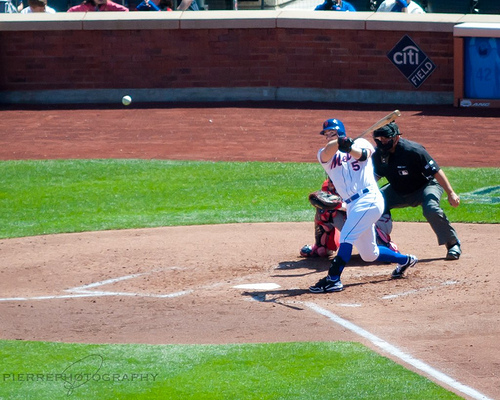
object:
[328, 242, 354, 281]
socks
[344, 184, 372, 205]
belt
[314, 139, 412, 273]
uniform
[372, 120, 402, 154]
facemask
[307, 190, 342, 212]
mitt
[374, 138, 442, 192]
shirt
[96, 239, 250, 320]
dirt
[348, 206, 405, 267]
legs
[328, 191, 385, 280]
legs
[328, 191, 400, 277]
pants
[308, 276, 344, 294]
athletic shoe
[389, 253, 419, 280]
athletic shoe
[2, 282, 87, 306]
foul line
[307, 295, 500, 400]
foul line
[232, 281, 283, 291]
baseball/home plate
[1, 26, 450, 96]
short/brick wall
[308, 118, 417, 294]
baseball player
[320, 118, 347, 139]
blue helmet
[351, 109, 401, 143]
bat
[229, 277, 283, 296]
white pentagon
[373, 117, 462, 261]
catcher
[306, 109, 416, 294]
batter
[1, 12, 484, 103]
brick wall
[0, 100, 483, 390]
field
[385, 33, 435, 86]
citi-field-sign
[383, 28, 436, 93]
sign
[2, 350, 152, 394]
company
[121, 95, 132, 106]
ball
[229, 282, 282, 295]
plate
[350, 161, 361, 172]
number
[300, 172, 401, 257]
catcher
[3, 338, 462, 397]
grass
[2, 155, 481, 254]
grass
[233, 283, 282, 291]
home plate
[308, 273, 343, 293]
shoe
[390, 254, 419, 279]
shoe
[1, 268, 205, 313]
line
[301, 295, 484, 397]
line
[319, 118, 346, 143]
head